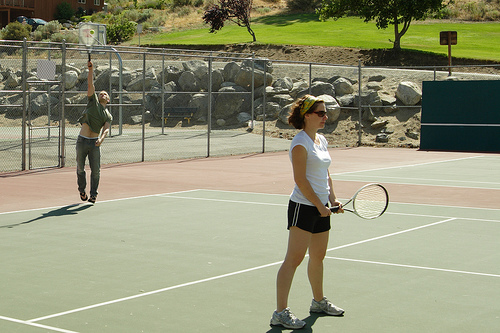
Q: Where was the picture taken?
A: On a tennis court.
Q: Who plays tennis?
A: Tennis players.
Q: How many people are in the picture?
A: 2.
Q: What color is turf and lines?
A: Green and white.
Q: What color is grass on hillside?
A: Green.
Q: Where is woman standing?
A: On tennis court.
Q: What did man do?
A: Jumped in air.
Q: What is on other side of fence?
A: Boulders.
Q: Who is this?
A: A woman.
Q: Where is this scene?
A: A tennis court.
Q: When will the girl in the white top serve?
A: At rotation.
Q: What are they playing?
A: Tennis.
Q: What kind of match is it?
A: Doubles.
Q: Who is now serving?
A: The person at the line.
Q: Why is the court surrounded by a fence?
A: To contain the balls.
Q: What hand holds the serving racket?
A: The right.